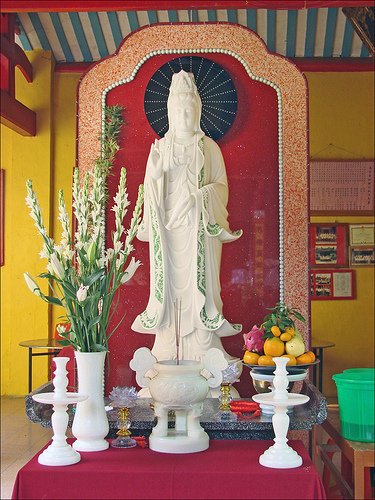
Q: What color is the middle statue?
A: Off white.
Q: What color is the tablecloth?
A: Red.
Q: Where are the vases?
A: Table.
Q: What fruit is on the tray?
A: Oranges.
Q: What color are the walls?
A: Yellow.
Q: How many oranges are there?
A: Six.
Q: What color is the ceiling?
A: Blue and white.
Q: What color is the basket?
A: Green.